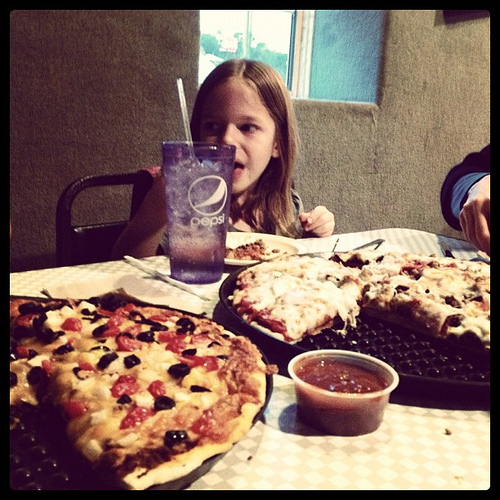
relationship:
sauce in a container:
[294, 362, 386, 436] [286, 347, 398, 437]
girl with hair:
[163, 48, 343, 270] [158, 50, 332, 134]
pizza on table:
[239, 251, 491, 336] [17, 245, 497, 392]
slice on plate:
[225, 238, 275, 263] [188, 225, 301, 270]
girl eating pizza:
[103, 53, 342, 261] [217, 234, 270, 266]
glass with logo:
[160, 142, 235, 283] [187, 174, 228, 215]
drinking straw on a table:
[172, 74, 202, 161] [62, 137, 457, 426]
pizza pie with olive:
[2, 276, 265, 487] [124, 350, 140, 366]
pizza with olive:
[64, 286, 260, 450] [164, 426, 189, 445]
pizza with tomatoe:
[64, 286, 260, 450] [149, 378, 163, 394]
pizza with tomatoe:
[64, 286, 260, 450] [194, 355, 214, 367]